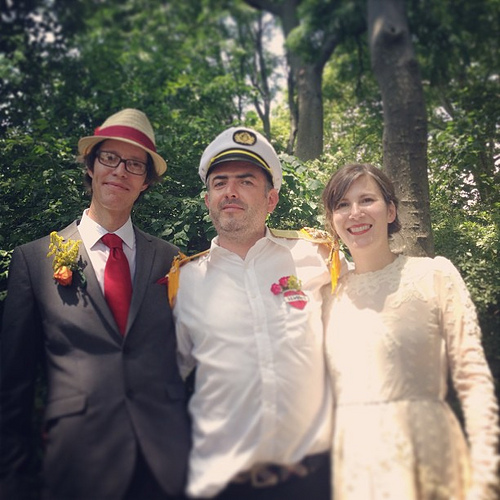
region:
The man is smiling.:
[66, 104, 173, 228]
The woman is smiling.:
[322, 150, 419, 280]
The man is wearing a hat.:
[68, 100, 176, 222]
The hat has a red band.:
[72, 92, 182, 218]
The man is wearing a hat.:
[190, 115, 294, 245]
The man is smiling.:
[186, 113, 289, 245]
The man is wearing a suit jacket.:
[0, 104, 188, 497]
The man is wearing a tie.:
[6, 103, 178, 370]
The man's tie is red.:
[20, 102, 179, 343]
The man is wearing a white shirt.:
[52, 103, 169, 358]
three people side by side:
[13, 107, 486, 497]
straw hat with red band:
[78, 106, 165, 175]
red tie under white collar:
[98, 225, 132, 324]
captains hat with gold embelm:
[195, 127, 287, 184]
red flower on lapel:
[55, 255, 111, 324]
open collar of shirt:
[203, 232, 283, 274]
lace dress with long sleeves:
[328, 258, 495, 498]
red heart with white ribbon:
[283, 287, 308, 312]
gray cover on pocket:
[39, 392, 87, 424]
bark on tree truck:
[390, 117, 430, 254]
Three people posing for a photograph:
[6, 103, 496, 496]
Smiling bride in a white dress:
[319, 160, 499, 495]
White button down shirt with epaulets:
[178, 221, 335, 497]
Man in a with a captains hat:
[173, 123, 335, 498]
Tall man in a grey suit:
[6, 108, 184, 498]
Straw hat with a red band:
[76, 105, 168, 177]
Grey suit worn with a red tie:
[6, 224, 191, 499]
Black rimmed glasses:
[86, 148, 151, 177]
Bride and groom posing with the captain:
[2, 3, 499, 496]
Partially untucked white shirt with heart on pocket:
[176, 230, 335, 495]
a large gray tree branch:
[357, 5, 438, 255]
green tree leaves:
[271, 150, 321, 225]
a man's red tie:
[97, 227, 132, 327]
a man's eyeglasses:
[87, 145, 147, 180]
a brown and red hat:
[77, 102, 169, 179]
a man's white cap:
[198, 124, 283, 200]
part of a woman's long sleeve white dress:
[318, 254, 498, 499]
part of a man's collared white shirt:
[79, 203, 140, 313]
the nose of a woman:
[345, 203, 366, 221]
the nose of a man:
[217, 181, 244, 201]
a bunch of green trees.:
[0, 1, 499, 105]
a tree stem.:
[360, 2, 445, 148]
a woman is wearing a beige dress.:
[350, 378, 419, 458]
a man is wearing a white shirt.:
[237, 322, 294, 406]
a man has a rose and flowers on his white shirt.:
[268, 265, 318, 317]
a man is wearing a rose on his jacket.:
[40, 223, 89, 298]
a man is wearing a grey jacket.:
[8, 288, 171, 498]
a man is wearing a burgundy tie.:
[99, 260, 138, 301]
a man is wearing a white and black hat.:
[192, 123, 290, 187]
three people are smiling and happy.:
[3, 80, 497, 498]